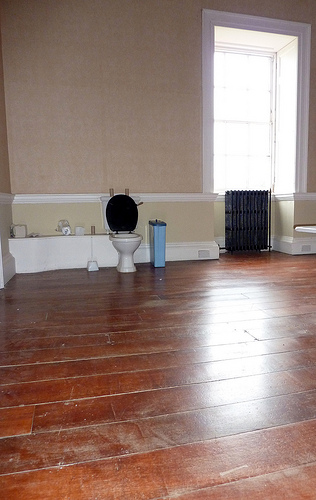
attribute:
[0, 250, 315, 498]
floor — dusty, wood, wooden, brown, dirty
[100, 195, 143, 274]
toilet — porcelain, white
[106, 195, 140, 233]
seat cover — black, porcelain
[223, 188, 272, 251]
radiator — black, silver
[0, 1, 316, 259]
wall — blank, tan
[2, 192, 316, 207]
molding — white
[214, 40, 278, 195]
window — sunny, tall, large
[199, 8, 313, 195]
frame — wooden, white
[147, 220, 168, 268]
trash can — blue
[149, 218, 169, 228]
lid — black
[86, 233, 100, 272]
toilet cleaner — white, plastic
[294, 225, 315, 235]
bath tub — white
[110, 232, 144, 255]
bowl — white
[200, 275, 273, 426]
reflection — on wood, from light, glaring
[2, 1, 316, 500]
room — empty